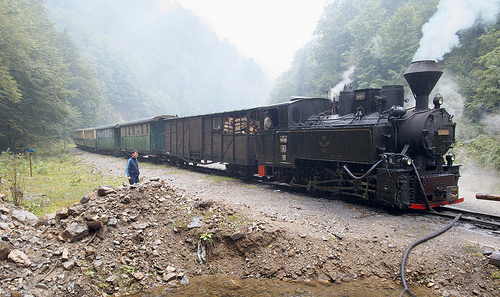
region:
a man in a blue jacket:
[124, 147, 142, 186]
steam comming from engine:
[405, 0, 498, 63]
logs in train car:
[217, 113, 262, 139]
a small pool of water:
[91, 267, 452, 294]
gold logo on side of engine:
[312, 128, 335, 160]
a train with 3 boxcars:
[68, 57, 468, 216]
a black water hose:
[340, 152, 466, 295]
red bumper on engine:
[411, 192, 467, 214]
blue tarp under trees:
[21, 143, 38, 154]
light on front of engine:
[429, 90, 446, 113]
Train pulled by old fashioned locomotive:
[3, 21, 474, 225]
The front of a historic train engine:
[403, 48, 468, 217]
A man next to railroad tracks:
[88, 121, 238, 206]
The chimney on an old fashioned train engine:
[403, 40, 455, 96]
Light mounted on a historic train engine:
[431, 91, 451, 111]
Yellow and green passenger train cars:
[70, 100, 165, 156]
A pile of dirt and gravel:
[50, 180, 205, 290]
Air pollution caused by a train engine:
[87, 10, 482, 85]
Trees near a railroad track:
[10, 6, 115, 163]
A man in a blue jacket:
[116, 147, 146, 188]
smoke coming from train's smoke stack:
[411, 17, 480, 79]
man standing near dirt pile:
[124, 140, 145, 190]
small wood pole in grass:
[19, 143, 47, 178]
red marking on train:
[245, 161, 279, 179]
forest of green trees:
[8, 8, 163, 110]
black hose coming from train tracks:
[394, 212, 475, 284]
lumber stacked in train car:
[222, 103, 283, 133]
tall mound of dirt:
[86, 180, 319, 265]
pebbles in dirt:
[17, 236, 117, 273]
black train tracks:
[448, 201, 498, 228]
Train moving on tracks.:
[78, 56, 475, 213]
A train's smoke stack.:
[398, 44, 457, 111]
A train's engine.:
[246, 52, 468, 216]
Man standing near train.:
[118, 144, 150, 194]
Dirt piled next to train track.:
[26, 175, 353, 295]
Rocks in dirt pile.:
[49, 209, 108, 241]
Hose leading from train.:
[343, 158, 465, 295]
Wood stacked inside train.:
[218, 112, 261, 142]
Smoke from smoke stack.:
[411, 1, 489, 69]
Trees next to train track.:
[1, 6, 82, 158]